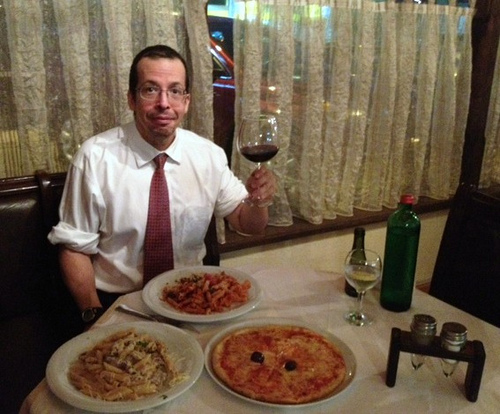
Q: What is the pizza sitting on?
A: A plate.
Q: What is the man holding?
A: A glass of wine.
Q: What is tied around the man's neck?
A: A tie.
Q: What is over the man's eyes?
A: Glasses.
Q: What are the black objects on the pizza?
A: Olives.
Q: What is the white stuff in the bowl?
A: Pasta.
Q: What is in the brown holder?
A: Salt and pepper shakers.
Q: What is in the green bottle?
A: Wine.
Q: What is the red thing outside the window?
A: A car.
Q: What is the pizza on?
A: Plate.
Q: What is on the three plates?
A: Food.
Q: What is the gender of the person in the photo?
A: A man.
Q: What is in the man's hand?
A: Glass.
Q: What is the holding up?
A: Glass of wine.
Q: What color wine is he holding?
A: Red.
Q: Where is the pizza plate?
A: Center of the table.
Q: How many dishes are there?
A: Three.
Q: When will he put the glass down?
A: After a sip.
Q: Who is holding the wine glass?
A: The gentleman with a tie.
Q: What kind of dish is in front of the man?
A: Pasta.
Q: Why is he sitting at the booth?
A: Ready to eat.